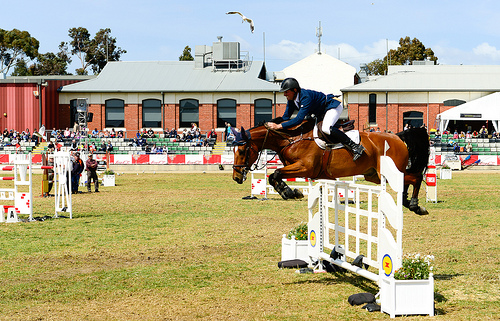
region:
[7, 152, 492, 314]
obstacle course on dried tan and green grass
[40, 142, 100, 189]
people standing between obstacles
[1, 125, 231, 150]
spectators and empty seats behind partition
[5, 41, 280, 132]
striped and brick building behind spectators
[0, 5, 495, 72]
blue sky with white puffy clouds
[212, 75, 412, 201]
horse and rider jumping over gridded fence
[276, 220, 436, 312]
planters filled with flowers at ends of fence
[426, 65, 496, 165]
large white tent and brick building behind seating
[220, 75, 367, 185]
rider leaning forward over horse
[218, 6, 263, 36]
bird with wings curved downward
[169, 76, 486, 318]
a horse that is jumping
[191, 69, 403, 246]
a brown horse that is jumping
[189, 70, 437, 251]
a man sitting on horse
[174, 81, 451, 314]
a man sitting on brown horse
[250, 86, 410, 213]
a man riding a horse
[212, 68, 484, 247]
a man riding a brown horse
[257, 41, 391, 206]
a man wearing a helmet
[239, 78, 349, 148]
a man wearing a black helmet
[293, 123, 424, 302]
a white baracade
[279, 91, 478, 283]
a horse that is outside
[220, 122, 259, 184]
head of a horse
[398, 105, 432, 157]
tail of a horse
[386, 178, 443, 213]
leg of a horse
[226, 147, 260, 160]
eye of a horse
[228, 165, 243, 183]
mouth of a horse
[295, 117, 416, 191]
body of a horse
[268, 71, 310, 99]
head of a person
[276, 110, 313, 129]
arm of a person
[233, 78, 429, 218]
a brown jumping horse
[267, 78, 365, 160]
a male jockey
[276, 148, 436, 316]
a white jumping fence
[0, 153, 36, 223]
a white jumping fence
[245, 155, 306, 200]
a white jumping fence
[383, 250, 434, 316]
a flower planter with white flowers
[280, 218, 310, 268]
a flower planter with white flowers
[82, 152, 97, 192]
a person standing on field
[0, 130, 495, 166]
arena spectator seating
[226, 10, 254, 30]
a white and black seabird in air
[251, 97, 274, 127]
window on a large brick building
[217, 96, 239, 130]
window on a large brick building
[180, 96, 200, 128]
window on a large brick building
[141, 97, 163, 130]
window on a large brick building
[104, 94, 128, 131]
window on a large brick building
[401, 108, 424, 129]
window on a large brick building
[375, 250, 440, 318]
flowers in a white planter box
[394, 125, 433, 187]
black tail of a brown horse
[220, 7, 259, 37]
white bird flying in the sky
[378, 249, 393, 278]
yellow and blue logo